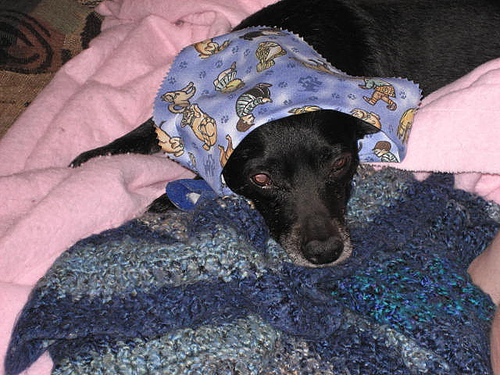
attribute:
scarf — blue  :
[225, 80, 276, 132]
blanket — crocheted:
[2, 166, 499, 373]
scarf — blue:
[149, 23, 424, 203]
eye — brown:
[247, 162, 274, 190]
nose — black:
[303, 225, 344, 263]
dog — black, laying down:
[78, 17, 493, 267]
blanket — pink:
[4, 4, 461, 356]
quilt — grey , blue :
[4, 163, 499, 374]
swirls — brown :
[0, 10, 50, 72]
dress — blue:
[99, 237, 272, 334]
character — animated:
[236, 84, 272, 119]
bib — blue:
[158, 43, 429, 174]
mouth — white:
[292, 252, 354, 265]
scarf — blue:
[153, 32, 413, 167]